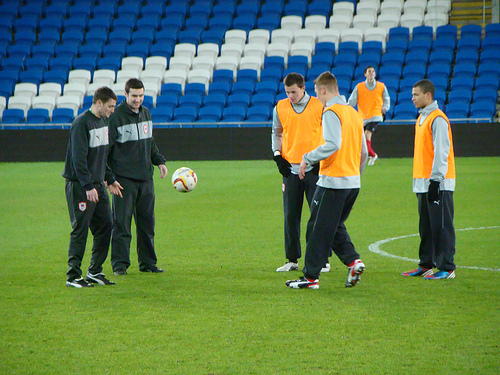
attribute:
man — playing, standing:
[104, 76, 169, 277]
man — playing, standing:
[62, 85, 125, 289]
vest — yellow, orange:
[273, 95, 327, 165]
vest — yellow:
[319, 102, 364, 177]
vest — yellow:
[411, 107, 457, 179]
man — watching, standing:
[402, 79, 459, 280]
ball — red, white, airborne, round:
[173, 167, 199, 193]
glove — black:
[271, 155, 293, 177]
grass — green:
[230, 211, 231, 212]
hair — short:
[413, 80, 438, 100]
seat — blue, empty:
[213, 68, 235, 84]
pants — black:
[111, 171, 157, 269]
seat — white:
[216, 55, 239, 81]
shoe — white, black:
[283, 275, 321, 291]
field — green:
[1, 157, 499, 374]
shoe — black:
[137, 263, 166, 275]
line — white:
[366, 226, 499, 271]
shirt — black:
[62, 108, 117, 189]